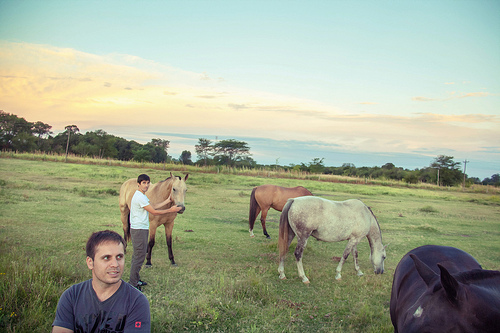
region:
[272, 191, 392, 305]
this is a horse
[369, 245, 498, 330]
this is a horse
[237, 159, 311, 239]
this is a horse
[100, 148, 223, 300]
this is a horse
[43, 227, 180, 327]
this is a person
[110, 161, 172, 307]
this is a person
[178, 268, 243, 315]
this is grass on the ground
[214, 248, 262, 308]
this is grass on the ground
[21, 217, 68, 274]
this is grass on the ground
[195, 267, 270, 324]
this is grass on the ground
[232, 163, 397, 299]
two horses grazing in the grass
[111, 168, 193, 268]
horse standing in the grass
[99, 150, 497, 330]
a group of four horses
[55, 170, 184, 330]
two men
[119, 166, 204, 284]
man standing by the horse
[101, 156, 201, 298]
man touching the horse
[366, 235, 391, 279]
head bent down to the ground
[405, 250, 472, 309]
two pointy ears on top of the head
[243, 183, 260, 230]
long dark hair on the tail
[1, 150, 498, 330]
green grass on the ground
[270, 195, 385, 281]
A horse eating green grass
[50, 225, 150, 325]
A man in a blue shirt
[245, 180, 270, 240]
Backside of a brown horse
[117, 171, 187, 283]
A man pets a brown horse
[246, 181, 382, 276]
Two horse with their snout near the ground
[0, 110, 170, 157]
Dark green foliage in the distance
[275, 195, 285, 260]
Long, hairy tail of a horse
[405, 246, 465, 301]
A black horse's ears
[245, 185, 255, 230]
The tail of a brown horse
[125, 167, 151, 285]
Man standing beside a horse.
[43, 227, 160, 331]
man standing in grassy field near horses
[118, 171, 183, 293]
man wearing white shirt standing in field next to horse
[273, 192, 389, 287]
white and gray horse eating grass in field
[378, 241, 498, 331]
dark brown horse standing in field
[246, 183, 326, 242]
brown horse standing in grassy field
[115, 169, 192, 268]
light brown horse standing in green grassy field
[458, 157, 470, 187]
wooden telephone pole next to large field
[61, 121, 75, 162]
wooden pole at the edge of field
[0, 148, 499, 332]
large green grassy field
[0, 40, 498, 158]
thin white sheet of clouds in light blue sky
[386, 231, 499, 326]
brown horse starring at man in front of picture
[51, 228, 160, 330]
man in blue shirt starring at black horse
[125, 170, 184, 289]
man in white shirt petting horse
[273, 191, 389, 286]
white horse grazing grass in field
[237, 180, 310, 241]
brown horse grazing grass behind white horse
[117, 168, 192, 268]
brown horse being rubbed by man in white shirt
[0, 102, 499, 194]
trees in background outlining field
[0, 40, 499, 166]
white clouds in sky above tree line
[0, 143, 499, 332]
grass underneath the horses and humans in open field